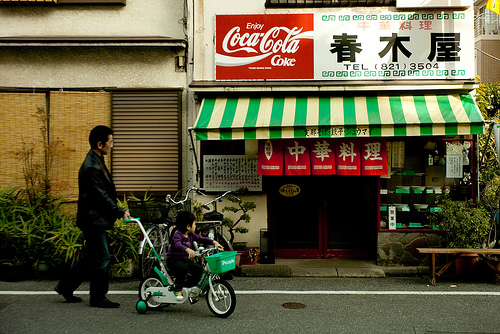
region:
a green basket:
[201, 248, 240, 270]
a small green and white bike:
[116, 207, 237, 316]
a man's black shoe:
[87, 295, 122, 309]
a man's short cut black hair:
[83, 123, 115, 147]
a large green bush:
[0, 184, 69, 271]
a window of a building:
[112, 92, 180, 199]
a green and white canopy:
[192, 97, 483, 139]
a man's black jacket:
[75, 149, 125, 229]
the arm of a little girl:
[170, 230, 191, 250]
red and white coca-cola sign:
[213, 11, 312, 83]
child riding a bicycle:
[126, 210, 254, 318]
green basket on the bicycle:
[204, 246, 239, 273]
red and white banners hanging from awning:
[256, 141, 388, 178]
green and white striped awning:
[188, 98, 481, 139]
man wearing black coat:
[61, 118, 133, 302]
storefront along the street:
[193, 6, 485, 270]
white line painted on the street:
[1, 281, 496, 297]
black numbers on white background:
[370, 60, 439, 71]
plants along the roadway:
[5, 183, 193, 281]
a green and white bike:
[128, 242, 246, 315]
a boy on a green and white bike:
[125, 204, 245, 321]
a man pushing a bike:
[53, 134, 243, 311]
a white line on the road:
[274, 290, 492, 297]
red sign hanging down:
[260, 140, 398, 177]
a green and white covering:
[198, 91, 488, 144]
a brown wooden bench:
[416, 243, 499, 283]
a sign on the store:
[208, 10, 482, 90]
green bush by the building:
[3, 115, 78, 272]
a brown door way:
[266, 172, 379, 263]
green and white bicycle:
[120, 208, 240, 323]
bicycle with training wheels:
[120, 210, 247, 320]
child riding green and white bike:
[157, 205, 227, 292]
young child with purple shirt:
[155, 205, 227, 290]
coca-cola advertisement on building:
[210, 10, 320, 80]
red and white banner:
[252, 135, 390, 178]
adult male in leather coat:
[46, 119, 137, 314]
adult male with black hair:
[46, 122, 131, 312]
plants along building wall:
[0, 170, 180, 280]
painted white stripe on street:
[1, 280, 498, 305]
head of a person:
[80, 111, 127, 164]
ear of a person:
[95, 138, 109, 150]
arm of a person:
[85, 180, 122, 212]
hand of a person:
[122, 210, 134, 222]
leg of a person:
[83, 234, 116, 281]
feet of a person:
[76, 292, 119, 322]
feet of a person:
[20, 288, 94, 309]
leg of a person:
[49, 248, 91, 306]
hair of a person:
[95, 120, 106, 140]